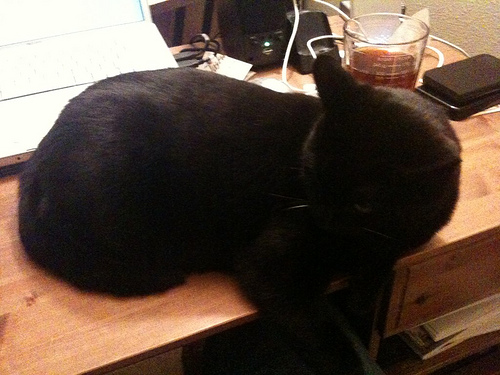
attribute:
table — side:
[1, 256, 499, 363]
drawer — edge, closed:
[399, 261, 499, 299]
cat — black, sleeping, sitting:
[27, 71, 462, 300]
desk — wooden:
[2, 230, 499, 345]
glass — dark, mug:
[342, 16, 431, 87]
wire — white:
[294, 10, 342, 68]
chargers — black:
[245, 14, 334, 61]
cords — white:
[274, 4, 464, 63]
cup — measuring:
[343, 39, 445, 78]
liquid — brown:
[356, 55, 405, 83]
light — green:
[259, 37, 271, 50]